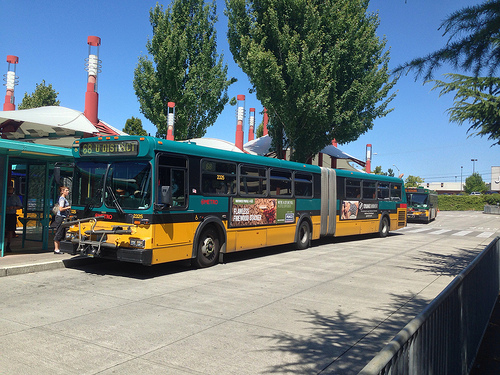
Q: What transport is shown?
A: A bus.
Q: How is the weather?
A: Sunny and clear.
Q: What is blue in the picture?
A: A sky.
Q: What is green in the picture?
A: Trees.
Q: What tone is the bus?
A: Blue and yellow.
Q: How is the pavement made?
A: Of concrete pavers.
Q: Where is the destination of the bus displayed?
A: The front.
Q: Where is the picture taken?
A: A bus stop.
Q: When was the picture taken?
A: Afternoon.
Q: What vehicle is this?
A: Bus.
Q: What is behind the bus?
A: Trees.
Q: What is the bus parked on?
A: Roadway.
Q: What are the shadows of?
A: Trees.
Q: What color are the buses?
A: Green and yellow.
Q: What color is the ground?
A: Gray.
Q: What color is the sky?
A: Blue.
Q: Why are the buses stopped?
A: To pick up passengers.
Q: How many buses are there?
A: Two.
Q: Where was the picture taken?
A: At at a bus stop.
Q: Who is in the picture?
A: Passengers.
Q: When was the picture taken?
A: In the daytime.